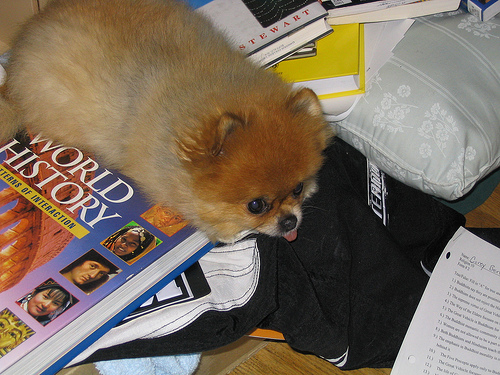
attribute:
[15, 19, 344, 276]
pomeranian — small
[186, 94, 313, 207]
dog — small, funny looking, sticking out tongue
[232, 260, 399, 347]
clothes — piled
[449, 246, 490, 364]
papers — stapled together, homework, white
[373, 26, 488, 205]
pillow — floral, without case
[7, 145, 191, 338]
book — world history, yellow, hard, history book, history, school book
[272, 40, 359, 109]
book — yellow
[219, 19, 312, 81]
books — stacked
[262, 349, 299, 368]
floor — brown, wooden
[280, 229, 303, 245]
tongue — pink, tiny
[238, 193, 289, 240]
eye — black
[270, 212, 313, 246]
nose — black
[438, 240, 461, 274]
paper — white, for school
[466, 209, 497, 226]
desk — wood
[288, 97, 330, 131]
ear — small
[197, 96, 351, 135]
ears — pointy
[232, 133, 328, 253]
face — tiny